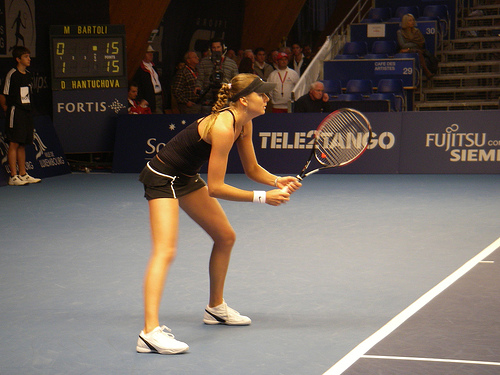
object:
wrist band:
[248, 187, 267, 205]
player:
[108, 53, 350, 363]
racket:
[279, 102, 375, 194]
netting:
[324, 118, 364, 154]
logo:
[321, 115, 359, 161]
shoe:
[137, 326, 195, 358]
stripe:
[137, 333, 160, 352]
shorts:
[141, 152, 205, 205]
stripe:
[146, 159, 178, 183]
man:
[263, 51, 312, 112]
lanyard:
[274, 68, 294, 98]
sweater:
[261, 65, 301, 106]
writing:
[60, 76, 126, 88]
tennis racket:
[275, 101, 372, 192]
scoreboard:
[42, 18, 130, 144]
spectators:
[126, 32, 314, 123]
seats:
[297, 72, 419, 111]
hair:
[202, 69, 277, 123]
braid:
[201, 71, 237, 132]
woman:
[139, 63, 304, 363]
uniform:
[136, 115, 238, 197]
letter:
[53, 98, 65, 116]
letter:
[64, 102, 73, 112]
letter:
[72, 100, 89, 112]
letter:
[84, 101, 96, 111]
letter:
[95, 96, 105, 112]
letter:
[448, 148, 463, 163]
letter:
[141, 133, 159, 154]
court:
[0, 165, 495, 373]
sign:
[56, 112, 496, 172]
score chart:
[47, 37, 122, 79]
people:
[128, 41, 316, 113]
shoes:
[135, 302, 250, 353]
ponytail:
[206, 79, 231, 112]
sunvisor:
[226, 76, 279, 101]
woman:
[398, 9, 433, 82]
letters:
[258, 128, 394, 153]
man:
[290, 79, 328, 110]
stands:
[295, 4, 495, 114]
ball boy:
[7, 47, 41, 189]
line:
[318, 234, 498, 373]